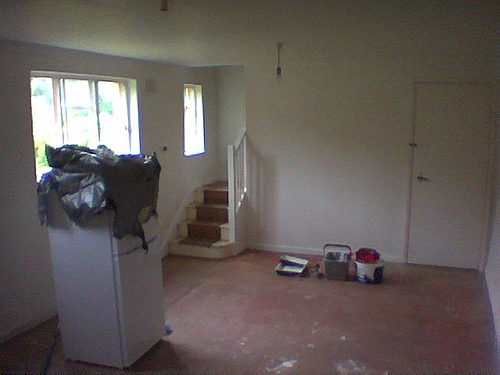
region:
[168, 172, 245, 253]
stairs going up to a new floor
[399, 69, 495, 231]
door in the wall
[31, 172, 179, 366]
fridge in the middle of the floor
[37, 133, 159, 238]
grey plastic tarp thrown on top of the fridge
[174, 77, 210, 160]
small window on the steps landing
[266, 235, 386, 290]
painting materials on the ground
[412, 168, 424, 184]
door knob on the door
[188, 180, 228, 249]
carpet on the steps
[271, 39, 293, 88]
light hanging down from the ceiling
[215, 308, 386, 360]
floor is cement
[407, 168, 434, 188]
doorknob on the door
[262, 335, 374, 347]
powder on the floor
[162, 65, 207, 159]
window on the wall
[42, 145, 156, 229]
clothes on the fridge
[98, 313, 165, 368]
fridge on the floor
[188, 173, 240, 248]
short kind of stairs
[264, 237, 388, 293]
items on the floor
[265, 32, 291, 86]
hanging from the ceiling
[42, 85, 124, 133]
the window is bright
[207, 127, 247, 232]
railing for the stairs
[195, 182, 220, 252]
brown rugs on steps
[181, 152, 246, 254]
white steps in room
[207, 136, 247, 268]
white rail on steps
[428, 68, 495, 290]
white door in room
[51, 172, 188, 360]
white fridge on floor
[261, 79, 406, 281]
white wall in room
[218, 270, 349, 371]
floor is reddish orange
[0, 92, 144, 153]
white frame on window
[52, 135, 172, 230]
black cover on fridge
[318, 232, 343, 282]
grey pail in room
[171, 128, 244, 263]
a wood staircase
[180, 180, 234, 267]
a rug down the center of the stairs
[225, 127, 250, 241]
a white railing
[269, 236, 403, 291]
painting supplies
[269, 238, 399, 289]
painting supplies on the floor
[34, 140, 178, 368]
a refrigerator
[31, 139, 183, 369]
a white refrigerator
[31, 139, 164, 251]
black garbage bags covering the top of the refrigerator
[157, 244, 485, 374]
the floor is red with white splashes of paint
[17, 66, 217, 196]
windows on the left wall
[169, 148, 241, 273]
Steps leading to the next floor.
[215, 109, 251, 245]
White railing on the steps.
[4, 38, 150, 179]
Windows that allow the sun in.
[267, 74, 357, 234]
Bare white wall in the room.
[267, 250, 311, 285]
Paint tray with a roller brush.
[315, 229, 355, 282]
Grey bucket with paint stains.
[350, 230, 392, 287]
Large bucket of paint.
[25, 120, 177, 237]
Plastic to cover the floor when painting.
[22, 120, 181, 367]
Fridge in the room.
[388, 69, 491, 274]
Closet door in the room.